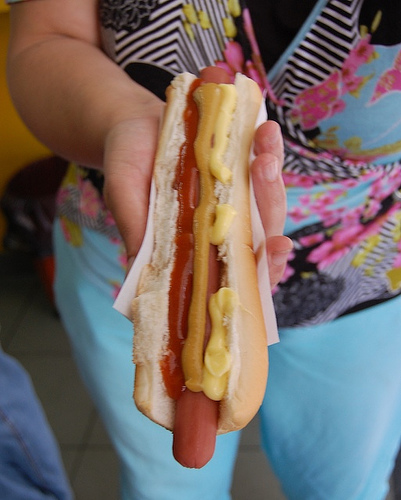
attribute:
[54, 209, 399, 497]
pants — blue, cotton,  blue,  person's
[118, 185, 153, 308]
napkin — white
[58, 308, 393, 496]
pants — blue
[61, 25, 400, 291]
top — multicolored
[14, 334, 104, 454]
tile —  white ,  stone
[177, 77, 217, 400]
mustard — dijon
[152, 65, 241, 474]
hot dog — long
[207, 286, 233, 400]
cheese — melted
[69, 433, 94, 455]
grout —  black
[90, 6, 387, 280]
shirt — bottom edge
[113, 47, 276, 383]
dog — footlong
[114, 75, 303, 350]
napkin —  white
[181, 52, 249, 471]
hot dog —  foot long,  with ketchup,  with mustard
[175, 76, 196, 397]
ketchup — red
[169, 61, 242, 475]
hot dog — footlong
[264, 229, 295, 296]
finger — index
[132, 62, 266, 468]
hot dog — long, footlong